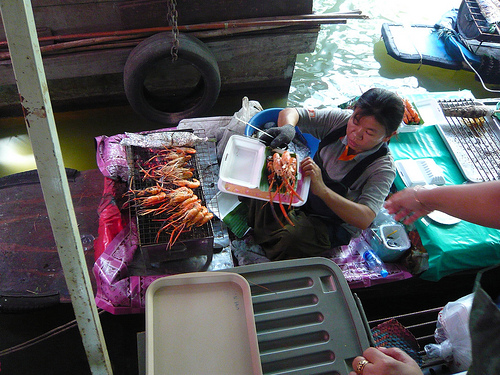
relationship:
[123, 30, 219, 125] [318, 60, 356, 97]
old tire hanging over water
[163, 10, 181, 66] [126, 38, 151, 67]
chain on tire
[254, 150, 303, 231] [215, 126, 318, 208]
seafood in styrofoam container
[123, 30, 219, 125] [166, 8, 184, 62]
old tire hanging from chain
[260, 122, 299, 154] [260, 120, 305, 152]
glove on hand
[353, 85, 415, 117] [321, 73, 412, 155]
dark hair on head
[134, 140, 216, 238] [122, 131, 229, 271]
shrimp on grill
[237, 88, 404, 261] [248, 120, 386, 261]
woman in apron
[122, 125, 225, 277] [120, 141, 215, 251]
grill with shrimp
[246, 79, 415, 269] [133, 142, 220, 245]
woman selling shrimp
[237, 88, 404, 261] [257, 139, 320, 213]
woman selling seafood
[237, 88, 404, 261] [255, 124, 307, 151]
woman wearing glove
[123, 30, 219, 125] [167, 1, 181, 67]
old tire hanging from chain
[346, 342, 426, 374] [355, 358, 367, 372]
hand with ring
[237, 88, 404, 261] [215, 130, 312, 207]
woman holding container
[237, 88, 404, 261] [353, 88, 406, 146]
woman with dark hair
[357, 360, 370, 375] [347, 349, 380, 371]
band on finger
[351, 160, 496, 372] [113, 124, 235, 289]
customer waiting to buy seafood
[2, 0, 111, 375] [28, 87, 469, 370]
support pole for dock